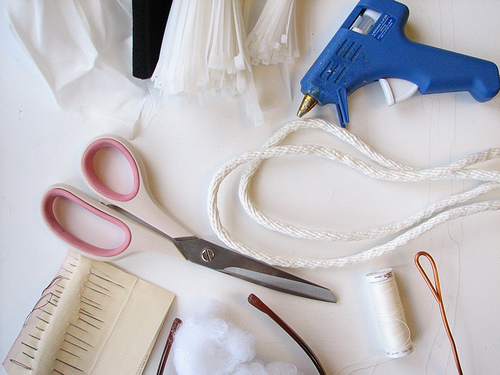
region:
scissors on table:
[31, 132, 338, 307]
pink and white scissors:
[36, 126, 343, 310]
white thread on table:
[361, 261, 418, 368]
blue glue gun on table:
[289, 1, 494, 128]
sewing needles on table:
[4, 249, 176, 374]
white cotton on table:
[172, 315, 315, 372]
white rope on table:
[201, 115, 497, 267]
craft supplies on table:
[36, 5, 498, 362]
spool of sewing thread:
[356, 265, 423, 362]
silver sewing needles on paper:
[18, 247, 159, 374]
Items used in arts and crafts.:
[13, 0, 493, 357]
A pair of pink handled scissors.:
[38, 130, 344, 314]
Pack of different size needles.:
[8, 249, 177, 373]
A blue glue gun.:
[293, 0, 499, 131]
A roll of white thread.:
[361, 265, 417, 363]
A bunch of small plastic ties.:
[249, 2, 311, 67]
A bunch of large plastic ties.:
[151, 0, 252, 102]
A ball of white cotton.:
[174, 315, 296, 373]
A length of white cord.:
[202, 110, 498, 275]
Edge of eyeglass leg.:
[246, 288, 329, 373]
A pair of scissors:
[43, 135, 338, 319]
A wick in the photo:
[222, 123, 449, 264]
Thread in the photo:
[363, 271, 408, 358]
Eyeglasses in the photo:
[161, 287, 315, 374]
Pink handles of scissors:
[29, 131, 130, 241]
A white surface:
[156, 121, 227, 173]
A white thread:
[370, 284, 412, 351]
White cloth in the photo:
[202, 25, 274, 92]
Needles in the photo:
[78, 277, 99, 349]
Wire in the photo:
[402, 237, 468, 362]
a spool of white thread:
[360, 265, 411, 360]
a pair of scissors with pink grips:
[38, 133, 338, 304]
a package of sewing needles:
[1, 247, 177, 372]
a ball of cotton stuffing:
[172, 315, 297, 372]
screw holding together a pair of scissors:
[198, 245, 213, 262]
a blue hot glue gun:
[293, 2, 496, 127]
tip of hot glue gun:
[292, 90, 314, 115]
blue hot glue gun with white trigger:
[295, 0, 496, 126]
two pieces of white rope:
[203, 115, 498, 266]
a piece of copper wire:
[413, 250, 466, 373]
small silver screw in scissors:
[193, 246, 222, 261]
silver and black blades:
[176, 239, 332, 308]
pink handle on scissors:
[31, 147, 172, 270]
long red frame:
[238, 279, 310, 342]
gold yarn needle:
[408, 247, 451, 306]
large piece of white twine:
[218, 133, 383, 226]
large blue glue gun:
[305, 22, 454, 102]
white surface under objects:
[160, 130, 215, 165]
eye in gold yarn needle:
[426, 263, 436, 279]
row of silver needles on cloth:
[79, 270, 117, 325]